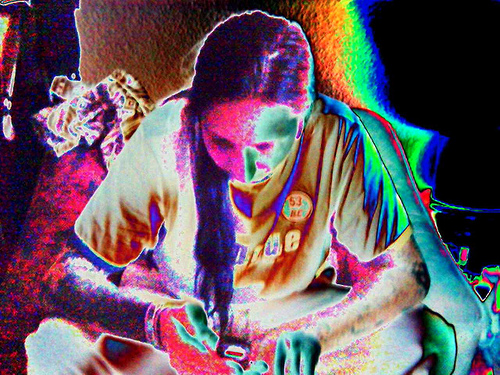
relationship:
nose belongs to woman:
[234, 148, 257, 184] [16, 13, 456, 373]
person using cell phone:
[41, 6, 439, 365] [213, 331, 253, 363]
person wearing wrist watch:
[41, 6, 439, 365] [137, 298, 168, 350]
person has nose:
[41, 6, 439, 365] [226, 147, 257, 181]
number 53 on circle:
[291, 194, 306, 206] [279, 185, 316, 221]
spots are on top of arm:
[57, 258, 149, 321] [53, 260, 182, 341]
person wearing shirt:
[22, 6, 437, 375] [138, 124, 402, 307]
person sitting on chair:
[22, 6, 437, 375] [48, 103, 482, 373]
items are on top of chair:
[31, 79, 142, 160] [51, 10, 410, 310]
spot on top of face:
[209, 100, 257, 158] [195, 78, 301, 198]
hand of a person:
[246, 322, 311, 367] [13, 20, 442, 372]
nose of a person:
[233, 151, 256, 183] [41, 6, 439, 365]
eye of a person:
[204, 133, 234, 158] [41, 6, 439, 365]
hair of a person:
[179, 11, 313, 334] [41, 6, 439, 365]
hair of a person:
[179, 13, 324, 353] [41, 6, 439, 365]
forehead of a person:
[188, 84, 300, 142] [13, 20, 442, 372]